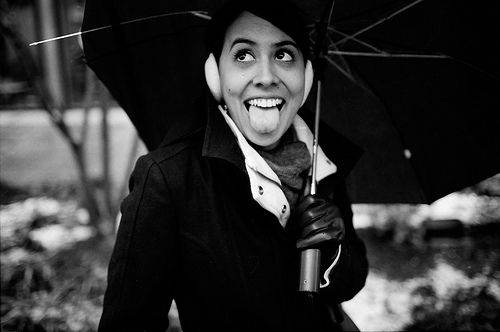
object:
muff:
[199, 49, 224, 107]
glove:
[288, 192, 347, 256]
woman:
[97, 3, 372, 332]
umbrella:
[80, 2, 498, 296]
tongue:
[247, 102, 282, 134]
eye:
[231, 48, 258, 63]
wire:
[22, 11, 180, 46]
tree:
[2, 2, 141, 239]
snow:
[1, 185, 96, 248]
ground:
[2, 167, 499, 331]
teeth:
[244, 96, 288, 109]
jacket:
[98, 107, 372, 332]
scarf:
[238, 137, 317, 207]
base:
[297, 246, 320, 291]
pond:
[0, 98, 499, 229]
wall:
[3, 3, 110, 109]